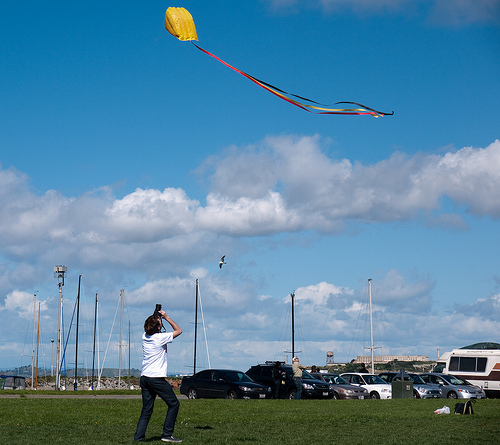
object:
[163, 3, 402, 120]
kite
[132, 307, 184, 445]
man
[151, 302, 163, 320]
camera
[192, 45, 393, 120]
tail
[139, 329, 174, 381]
shirt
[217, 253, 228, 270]
gull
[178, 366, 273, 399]
car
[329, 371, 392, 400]
car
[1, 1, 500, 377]
sky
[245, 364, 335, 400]
van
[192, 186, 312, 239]
clouds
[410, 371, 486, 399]
car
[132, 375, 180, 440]
pants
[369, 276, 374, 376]
pole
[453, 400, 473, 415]
bag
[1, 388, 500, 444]
ground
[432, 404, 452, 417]
bag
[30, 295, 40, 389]
mast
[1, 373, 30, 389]
boat